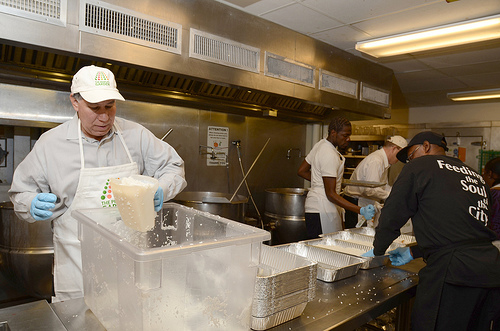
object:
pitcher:
[111, 172, 162, 232]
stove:
[246, 217, 308, 247]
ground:
[424, 158, 438, 193]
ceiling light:
[354, 15, 500, 60]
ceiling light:
[444, 88, 499, 101]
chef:
[8, 65, 188, 304]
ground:
[441, 165, 465, 197]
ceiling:
[215, 0, 500, 108]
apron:
[53, 120, 149, 300]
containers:
[264, 186, 309, 245]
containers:
[173, 191, 248, 241]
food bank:
[2, 1, 498, 331]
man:
[361, 130, 500, 331]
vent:
[360, 81, 391, 107]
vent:
[319, 67, 358, 102]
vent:
[265, 51, 318, 89]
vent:
[187, 28, 261, 74]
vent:
[82, 0, 182, 54]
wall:
[0, 1, 399, 230]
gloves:
[30, 191, 57, 221]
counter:
[1, 237, 421, 329]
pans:
[252, 243, 317, 329]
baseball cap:
[70, 65, 126, 104]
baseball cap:
[387, 135, 409, 148]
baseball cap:
[395, 131, 448, 165]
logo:
[94, 71, 111, 86]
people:
[342, 135, 410, 230]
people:
[297, 118, 375, 240]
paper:
[207, 125, 229, 166]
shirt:
[373, 155, 500, 289]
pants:
[439, 284, 499, 331]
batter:
[107, 173, 161, 233]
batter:
[307, 229, 402, 276]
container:
[74, 199, 272, 331]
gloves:
[154, 187, 164, 211]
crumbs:
[331, 279, 379, 306]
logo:
[100, 178, 117, 207]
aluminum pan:
[272, 242, 369, 283]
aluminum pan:
[298, 237, 390, 270]